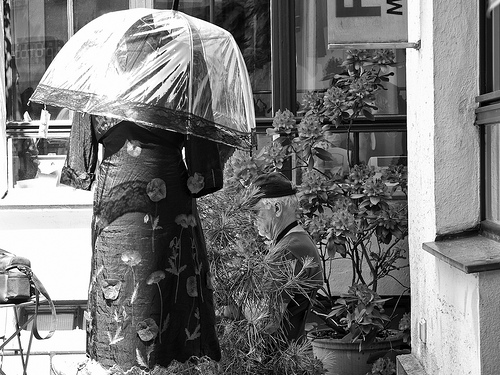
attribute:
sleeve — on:
[56, 96, 98, 192]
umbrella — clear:
[105, 34, 280, 159]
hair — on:
[256, 189, 298, 212]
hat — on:
[237, 162, 315, 222]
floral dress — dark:
[64, 105, 231, 373]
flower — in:
[314, 85, 356, 125]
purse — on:
[4, 264, 57, 341]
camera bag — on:
[0, 250, 57, 339]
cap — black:
[237, 172, 294, 209]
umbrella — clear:
[38, 9, 272, 160]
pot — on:
[310, 330, 402, 370]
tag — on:
[37, 105, 52, 145]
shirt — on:
[261, 232, 325, 287]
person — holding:
[64, 17, 239, 369]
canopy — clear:
[54, 11, 234, 111]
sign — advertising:
[320, 4, 445, 57]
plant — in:
[292, 155, 402, 322]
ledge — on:
[425, 208, 496, 291]